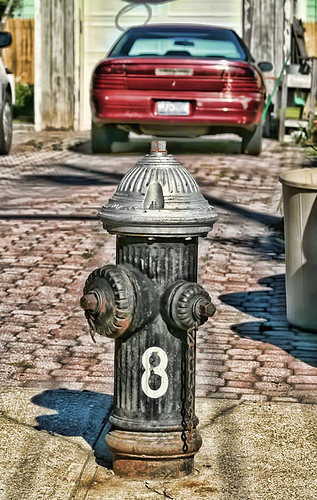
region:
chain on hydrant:
[185, 320, 198, 449]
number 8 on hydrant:
[137, 344, 171, 400]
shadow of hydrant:
[28, 383, 117, 475]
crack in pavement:
[197, 398, 246, 433]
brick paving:
[251, 369, 315, 404]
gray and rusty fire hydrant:
[80, 135, 217, 479]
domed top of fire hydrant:
[96, 139, 219, 241]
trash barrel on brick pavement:
[274, 162, 314, 335]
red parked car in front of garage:
[85, 16, 266, 152]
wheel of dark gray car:
[0, 69, 13, 155]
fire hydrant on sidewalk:
[0, 139, 316, 498]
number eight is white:
[140, 345, 169, 398]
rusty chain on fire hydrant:
[184, 324, 198, 441]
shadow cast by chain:
[178, 337, 188, 452]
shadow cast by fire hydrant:
[28, 386, 114, 469]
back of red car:
[87, 23, 267, 155]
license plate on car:
[155, 100, 191, 115]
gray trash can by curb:
[278, 166, 316, 329]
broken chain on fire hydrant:
[85, 313, 97, 343]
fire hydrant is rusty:
[78, 139, 219, 480]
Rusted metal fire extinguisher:
[80, 140, 217, 476]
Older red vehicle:
[89, 24, 265, 156]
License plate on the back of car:
[154, 99, 189, 116]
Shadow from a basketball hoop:
[112, 0, 173, 32]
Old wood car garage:
[35, 0, 285, 132]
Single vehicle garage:
[33, 0, 291, 137]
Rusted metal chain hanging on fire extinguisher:
[184, 322, 196, 443]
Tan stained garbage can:
[278, 166, 316, 329]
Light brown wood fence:
[0, 18, 33, 85]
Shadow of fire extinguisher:
[28, 386, 120, 467]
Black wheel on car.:
[235, 126, 259, 159]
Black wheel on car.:
[80, 108, 119, 163]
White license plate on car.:
[149, 87, 191, 122]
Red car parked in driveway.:
[117, 36, 242, 169]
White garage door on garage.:
[93, 9, 285, 101]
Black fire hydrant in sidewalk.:
[90, 235, 218, 445]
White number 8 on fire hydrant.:
[138, 331, 200, 467]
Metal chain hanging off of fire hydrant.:
[181, 323, 215, 447]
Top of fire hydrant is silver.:
[105, 126, 210, 242]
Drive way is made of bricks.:
[26, 166, 271, 308]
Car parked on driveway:
[91, 14, 266, 155]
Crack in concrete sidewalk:
[135, 475, 155, 498]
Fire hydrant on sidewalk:
[61, 152, 215, 497]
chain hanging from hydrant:
[166, 300, 202, 450]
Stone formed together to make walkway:
[13, 281, 79, 373]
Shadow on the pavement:
[32, 379, 137, 497]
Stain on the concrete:
[81, 462, 130, 497]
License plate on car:
[140, 88, 201, 132]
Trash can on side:
[262, 161, 315, 295]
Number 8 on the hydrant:
[134, 343, 173, 405]